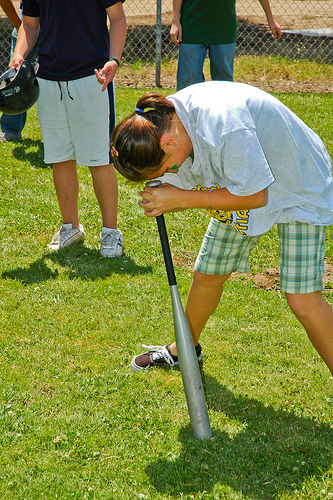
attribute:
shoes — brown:
[131, 341, 203, 369]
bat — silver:
[141, 178, 232, 444]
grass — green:
[1, 84, 322, 491]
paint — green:
[168, 161, 177, 171]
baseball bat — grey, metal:
[144, 182, 214, 437]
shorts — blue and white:
[35, 72, 121, 173]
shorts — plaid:
[190, 212, 331, 291]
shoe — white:
[95, 229, 124, 256]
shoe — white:
[48, 218, 83, 251]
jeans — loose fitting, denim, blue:
[158, 40, 240, 98]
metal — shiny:
[170, 283, 211, 440]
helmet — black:
[0, 59, 40, 117]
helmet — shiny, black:
[6, 56, 45, 114]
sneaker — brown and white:
[130, 341, 203, 368]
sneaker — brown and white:
[98, 226, 122, 256]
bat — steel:
[144, 180, 222, 437]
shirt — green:
[178, 9, 238, 46]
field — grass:
[2, 92, 330, 496]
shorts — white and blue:
[32, 72, 115, 164]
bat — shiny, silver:
[145, 177, 213, 441]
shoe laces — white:
[136, 333, 192, 372]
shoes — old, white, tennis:
[45, 221, 125, 262]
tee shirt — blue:
[19, 5, 122, 76]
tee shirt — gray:
[148, 81, 332, 236]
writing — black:
[181, 178, 252, 239]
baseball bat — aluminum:
[126, 175, 230, 458]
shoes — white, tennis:
[38, 192, 145, 263]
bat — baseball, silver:
[126, 181, 227, 442]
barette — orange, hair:
[110, 144, 117, 154]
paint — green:
[168, 162, 179, 172]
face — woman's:
[141, 155, 186, 178]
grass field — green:
[6, 263, 130, 490]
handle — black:
[148, 215, 177, 286]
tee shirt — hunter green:
[183, 2, 236, 44]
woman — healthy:
[105, 79, 321, 371]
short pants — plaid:
[198, 212, 323, 295]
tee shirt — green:
[178, 0, 239, 47]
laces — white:
[98, 227, 121, 248]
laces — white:
[48, 221, 74, 247]